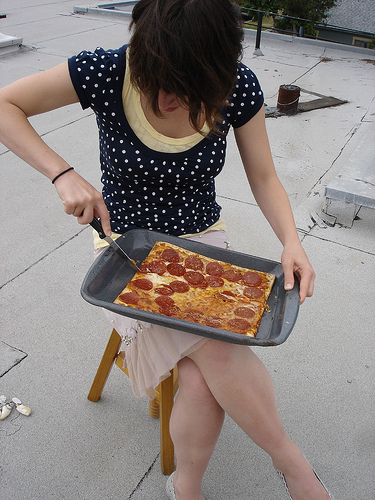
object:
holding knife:
[88, 212, 143, 273]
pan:
[80, 228, 300, 345]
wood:
[87, 327, 124, 405]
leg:
[86, 327, 122, 401]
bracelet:
[51, 166, 73, 183]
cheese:
[113, 238, 276, 344]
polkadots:
[149, 159, 155, 166]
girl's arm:
[1, 47, 93, 185]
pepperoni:
[130, 277, 154, 293]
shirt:
[62, 43, 265, 251]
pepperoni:
[233, 304, 255, 322]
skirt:
[100, 224, 236, 405]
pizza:
[112, 238, 277, 340]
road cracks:
[306, 205, 360, 232]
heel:
[165, 470, 175, 498]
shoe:
[164, 469, 205, 498]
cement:
[309, 331, 360, 413]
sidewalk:
[318, 0, 375, 38]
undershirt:
[92, 49, 230, 254]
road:
[0, 1, 372, 500]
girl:
[2, 1, 333, 500]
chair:
[87, 325, 180, 476]